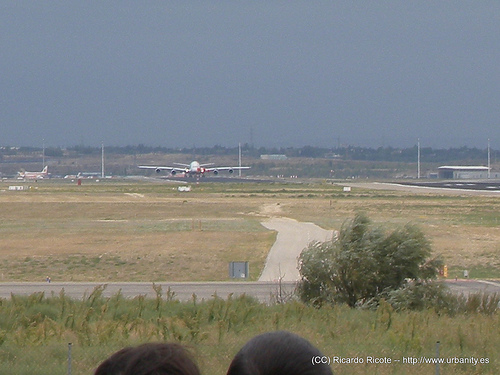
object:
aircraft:
[15, 165, 52, 183]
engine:
[213, 170, 219, 175]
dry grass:
[0, 180, 499, 284]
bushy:
[0, 265, 500, 350]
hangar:
[437, 165, 491, 181]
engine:
[170, 170, 177, 175]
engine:
[155, 168, 161, 173]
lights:
[200, 167, 204, 172]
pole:
[444, 265, 448, 278]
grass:
[0, 180, 500, 375]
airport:
[0, 146, 500, 305]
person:
[224, 331, 335, 374]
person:
[92, 341, 201, 374]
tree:
[295, 212, 445, 309]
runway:
[0, 278, 500, 306]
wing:
[137, 164, 191, 174]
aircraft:
[137, 161, 252, 181]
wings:
[138, 165, 251, 175]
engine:
[227, 168, 234, 174]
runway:
[379, 182, 498, 191]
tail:
[197, 166, 201, 171]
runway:
[257, 202, 340, 282]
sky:
[0, 0, 499, 148]